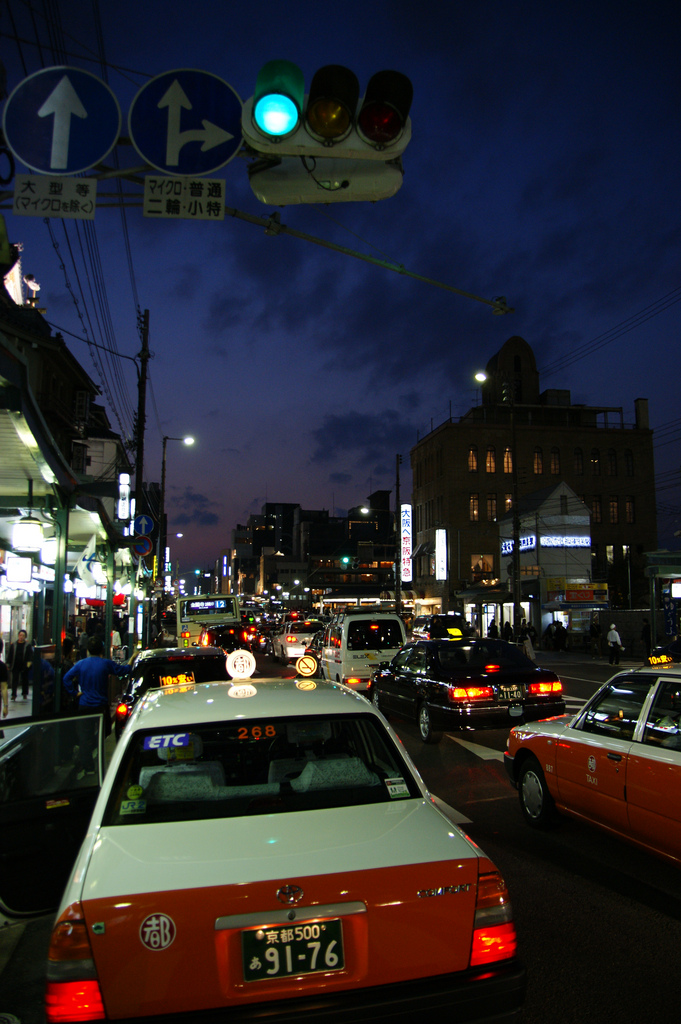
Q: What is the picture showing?
A: It is showing a street.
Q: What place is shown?
A: It is a street.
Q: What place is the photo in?
A: It is at the street.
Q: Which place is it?
A: It is a street.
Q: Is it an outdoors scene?
A: Yes, it is outdoors.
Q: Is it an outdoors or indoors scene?
A: It is outdoors.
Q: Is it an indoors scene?
A: No, it is outdoors.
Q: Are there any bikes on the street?
A: No, there is a car on the street.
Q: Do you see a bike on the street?
A: No, there is a car on the street.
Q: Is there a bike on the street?
A: No, there is a car on the street.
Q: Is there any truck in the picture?
A: No, there are no trucks.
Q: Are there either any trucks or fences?
A: No, there are no trucks or fences.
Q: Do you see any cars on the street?
A: Yes, there is a car on the street.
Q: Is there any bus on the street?
A: No, there is a car on the street.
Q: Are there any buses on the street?
A: No, there is a car on the street.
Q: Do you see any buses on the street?
A: No, there is a car on the street.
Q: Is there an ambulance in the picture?
A: No, there are no ambulances.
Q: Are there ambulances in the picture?
A: No, there are no ambulances.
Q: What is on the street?
A: The car is on the street.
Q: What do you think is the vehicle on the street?
A: The vehicle is a car.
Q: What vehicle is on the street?
A: The vehicle is a car.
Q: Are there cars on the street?
A: Yes, there is a car on the street.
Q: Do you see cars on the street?
A: Yes, there is a car on the street.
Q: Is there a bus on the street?
A: No, there is a car on the street.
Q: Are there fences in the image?
A: No, there are no fences.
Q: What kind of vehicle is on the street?
A: The vehicle is a car.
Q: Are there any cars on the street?
A: Yes, there is a car on the street.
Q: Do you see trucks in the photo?
A: No, there are no trucks.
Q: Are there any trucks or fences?
A: No, there are no trucks or fences.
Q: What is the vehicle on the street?
A: The vehicle is a car.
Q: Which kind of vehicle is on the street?
A: The vehicle is a car.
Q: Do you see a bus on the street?
A: No, there is a car on the street.